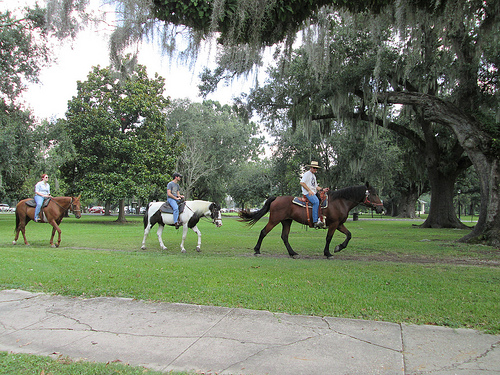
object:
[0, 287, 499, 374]
sidewalk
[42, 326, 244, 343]
cracks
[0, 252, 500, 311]
grass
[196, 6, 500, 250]
tree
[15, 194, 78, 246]
horse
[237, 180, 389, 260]
horse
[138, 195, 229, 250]
horse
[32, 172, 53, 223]
woman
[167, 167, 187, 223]
man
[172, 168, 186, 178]
cap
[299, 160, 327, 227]
man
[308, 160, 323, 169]
hat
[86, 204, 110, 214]
car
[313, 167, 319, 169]
sunglasses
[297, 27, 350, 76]
moss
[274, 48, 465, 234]
trees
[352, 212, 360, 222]
can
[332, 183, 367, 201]
black main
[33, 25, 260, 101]
cloud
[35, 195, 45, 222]
jeans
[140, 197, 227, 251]
horses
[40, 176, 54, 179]
sunglasses